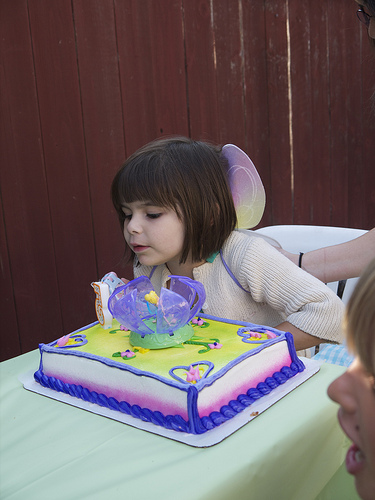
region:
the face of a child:
[321, 260, 373, 498]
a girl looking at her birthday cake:
[18, 134, 309, 443]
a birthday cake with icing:
[28, 276, 309, 438]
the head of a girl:
[96, 130, 243, 281]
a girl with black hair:
[95, 125, 240, 287]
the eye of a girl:
[141, 202, 167, 224]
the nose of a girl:
[124, 219, 142, 236]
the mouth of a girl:
[127, 237, 156, 254]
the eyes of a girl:
[114, 203, 168, 222]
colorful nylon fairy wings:
[222, 143, 276, 246]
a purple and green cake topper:
[110, 269, 201, 347]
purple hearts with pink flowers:
[160, 359, 210, 387]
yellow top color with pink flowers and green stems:
[56, 293, 244, 379]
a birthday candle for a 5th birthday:
[89, 275, 112, 325]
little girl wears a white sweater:
[193, 232, 352, 340]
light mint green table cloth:
[0, 347, 364, 495]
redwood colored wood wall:
[7, 4, 373, 351]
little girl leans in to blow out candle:
[93, 135, 239, 328]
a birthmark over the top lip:
[346, 420, 366, 437]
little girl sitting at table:
[74, 124, 349, 365]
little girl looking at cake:
[89, 130, 355, 373]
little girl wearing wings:
[212, 136, 284, 256]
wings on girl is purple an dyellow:
[215, 140, 288, 262]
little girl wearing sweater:
[110, 211, 344, 348]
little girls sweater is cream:
[112, 214, 352, 347]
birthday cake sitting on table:
[21, 259, 321, 450]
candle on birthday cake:
[89, 278, 114, 331]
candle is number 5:
[89, 277, 120, 328]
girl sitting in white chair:
[218, 213, 374, 366]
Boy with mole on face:
[328, 259, 373, 499]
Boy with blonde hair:
[325, 257, 374, 498]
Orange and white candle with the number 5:
[88, 279, 115, 329]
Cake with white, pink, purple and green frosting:
[22, 273, 320, 448]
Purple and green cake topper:
[106, 274, 204, 351]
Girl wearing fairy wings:
[109, 133, 346, 352]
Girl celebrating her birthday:
[107, 134, 346, 348]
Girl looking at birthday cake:
[106, 133, 347, 344]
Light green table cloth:
[2, 404, 337, 496]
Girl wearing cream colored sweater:
[102, 134, 342, 339]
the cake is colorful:
[44, 294, 296, 447]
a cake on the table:
[24, 273, 304, 460]